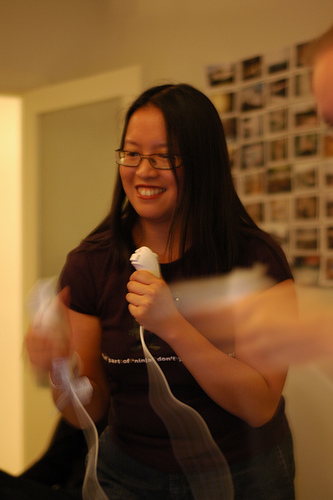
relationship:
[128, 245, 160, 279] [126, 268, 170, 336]
controller in hand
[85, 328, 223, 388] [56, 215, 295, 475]
slogan on shirt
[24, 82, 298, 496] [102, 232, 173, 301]
girl playing wii game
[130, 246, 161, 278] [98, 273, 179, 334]
controller in hand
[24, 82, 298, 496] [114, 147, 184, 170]
girl wearing framed glasses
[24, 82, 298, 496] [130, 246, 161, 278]
girl playing controller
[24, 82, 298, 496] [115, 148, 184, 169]
girl wearing glasses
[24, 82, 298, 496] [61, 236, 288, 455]
girl wearing shirt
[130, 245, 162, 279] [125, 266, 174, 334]
wii controller in hand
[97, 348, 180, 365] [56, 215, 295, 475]
lettering on a shirt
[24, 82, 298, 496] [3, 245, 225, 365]
girl holding controllers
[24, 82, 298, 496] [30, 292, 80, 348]
girl holding controller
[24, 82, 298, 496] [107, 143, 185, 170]
girl wearing framed glasses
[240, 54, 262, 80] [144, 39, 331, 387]
picture taped to wall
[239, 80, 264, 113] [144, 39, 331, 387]
picture taped to wall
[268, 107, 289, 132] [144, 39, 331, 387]
picture taped to wall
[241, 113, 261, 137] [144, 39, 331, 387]
picture taped to wall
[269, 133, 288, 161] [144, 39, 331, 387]
picture taped to wall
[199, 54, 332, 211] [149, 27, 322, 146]
wall photos on wall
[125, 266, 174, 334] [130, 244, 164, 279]
hand holding controller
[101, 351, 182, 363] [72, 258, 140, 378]
lettering on t-shirt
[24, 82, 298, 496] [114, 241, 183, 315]
girl holding controller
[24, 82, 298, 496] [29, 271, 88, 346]
girl holding controller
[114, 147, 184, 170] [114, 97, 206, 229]
framed glasses worn on face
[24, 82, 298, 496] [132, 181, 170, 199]
girl has smile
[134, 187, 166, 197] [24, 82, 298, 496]
teeth of girl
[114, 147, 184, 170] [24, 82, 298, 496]
framed glasses of girl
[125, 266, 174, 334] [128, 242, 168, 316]
hand holding controller